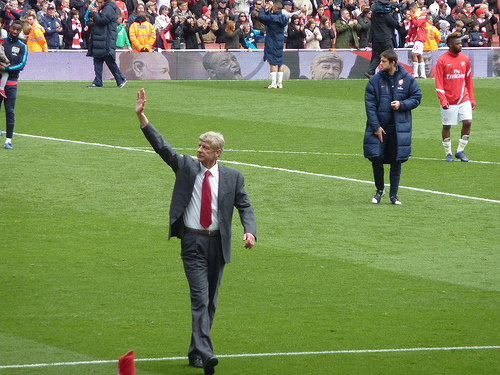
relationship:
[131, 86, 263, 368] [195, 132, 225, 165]
man has head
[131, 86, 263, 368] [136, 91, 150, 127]
man has hand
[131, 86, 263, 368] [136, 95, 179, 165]
man has arm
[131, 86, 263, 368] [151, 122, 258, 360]
man wears suit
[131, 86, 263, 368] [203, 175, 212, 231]
man wears tie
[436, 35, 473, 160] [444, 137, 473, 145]
man wears shin guards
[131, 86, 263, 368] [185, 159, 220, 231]
man wears shirt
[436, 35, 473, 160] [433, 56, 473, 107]
man wears shirt